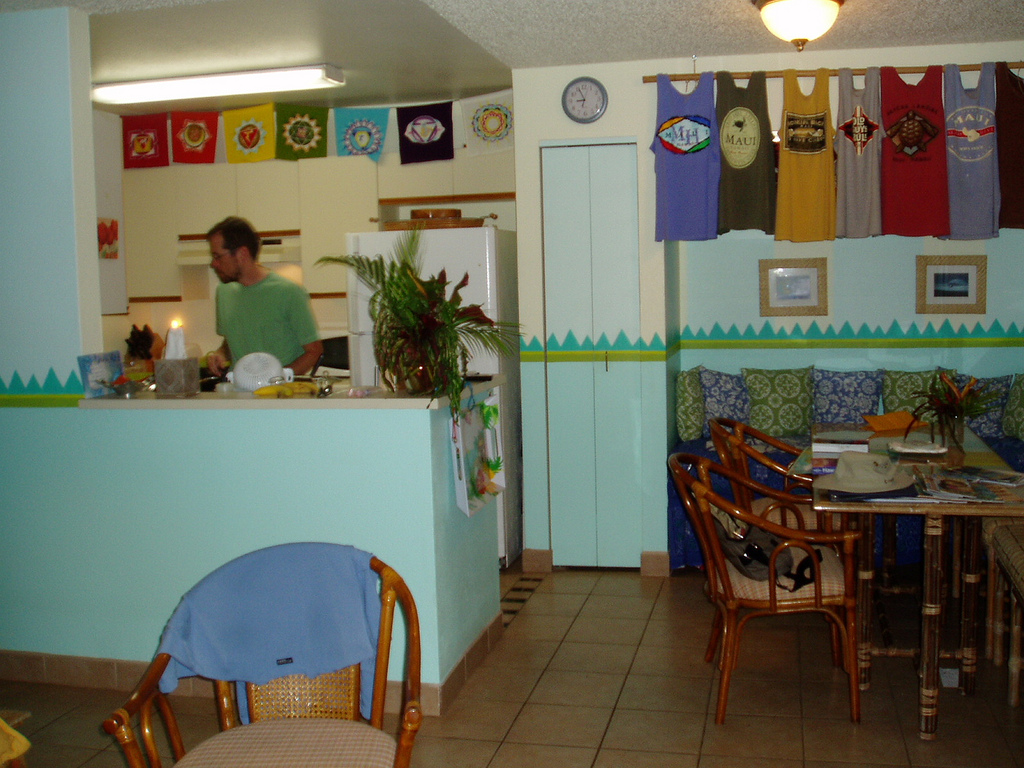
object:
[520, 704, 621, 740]
tile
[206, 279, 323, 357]
green shirt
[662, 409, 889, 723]
set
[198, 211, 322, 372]
man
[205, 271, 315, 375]
shirt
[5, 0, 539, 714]
kitchen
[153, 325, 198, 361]
tissue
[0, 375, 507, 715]
counter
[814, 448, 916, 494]
hat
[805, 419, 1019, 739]
table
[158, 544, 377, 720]
cloth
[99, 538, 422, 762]
chair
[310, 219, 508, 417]
plant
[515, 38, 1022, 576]
wall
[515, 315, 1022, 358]
trim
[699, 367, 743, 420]
pillow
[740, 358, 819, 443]
pillow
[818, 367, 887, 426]
pillow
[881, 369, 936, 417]
pillow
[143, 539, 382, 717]
shirt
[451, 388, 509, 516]
picture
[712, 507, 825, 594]
bag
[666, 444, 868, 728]
chair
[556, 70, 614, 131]
clock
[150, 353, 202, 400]
tissue box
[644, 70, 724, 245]
shirt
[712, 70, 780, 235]
shirt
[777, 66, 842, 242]
shirt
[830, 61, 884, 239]
shirt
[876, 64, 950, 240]
shirt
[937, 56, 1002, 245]
shirt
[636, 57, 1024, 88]
bar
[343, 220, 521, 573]
refrigerator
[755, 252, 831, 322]
picture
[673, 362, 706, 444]
pillow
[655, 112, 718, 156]
maui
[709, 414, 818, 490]
chair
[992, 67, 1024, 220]
shirts